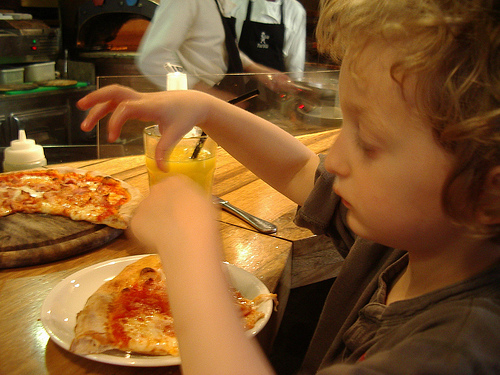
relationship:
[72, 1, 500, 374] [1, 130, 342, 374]
boy near table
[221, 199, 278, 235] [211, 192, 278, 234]
handle of utensil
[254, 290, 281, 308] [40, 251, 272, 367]
cheese going over edge of plate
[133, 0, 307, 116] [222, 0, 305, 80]
people wearing shirt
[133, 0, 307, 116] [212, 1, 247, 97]
people wearing apron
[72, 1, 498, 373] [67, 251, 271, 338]
boy eating pizza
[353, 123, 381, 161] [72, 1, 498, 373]
eye of boy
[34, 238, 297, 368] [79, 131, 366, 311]
plate on table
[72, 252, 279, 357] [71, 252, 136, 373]
pizza on a plate